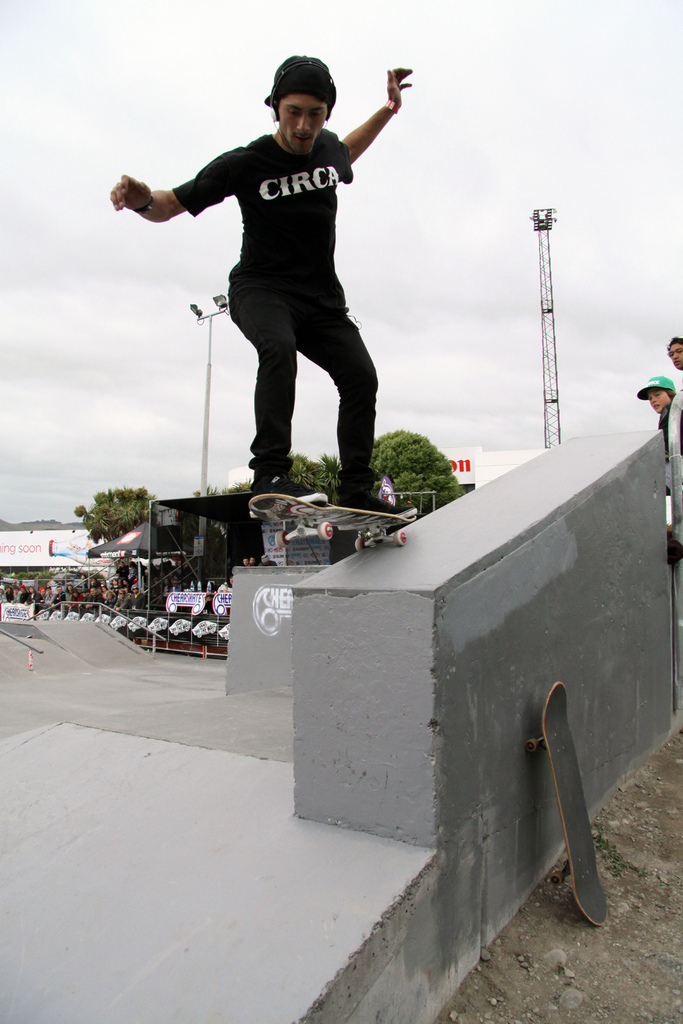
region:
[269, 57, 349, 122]
Boy wearing black hat.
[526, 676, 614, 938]
Skateboard leaning on wall.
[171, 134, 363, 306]
Boy wearing black shirt.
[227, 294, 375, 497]
Boy wearing black pants.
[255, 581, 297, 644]
White letters on wall.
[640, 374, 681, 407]
Person wearing green hat.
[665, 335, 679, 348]
Person has dark hair.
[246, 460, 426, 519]
Person wearing black tennis shoes.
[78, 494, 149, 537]
Green leaves on tree in distance.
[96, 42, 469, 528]
a guy doing a trick on a skateboard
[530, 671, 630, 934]
a skateboard leaning against the wall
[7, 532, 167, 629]
spectators sitting in a stand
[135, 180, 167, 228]
a black watch band on his wrist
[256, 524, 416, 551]
white and red wheels on the skateboard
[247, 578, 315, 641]
white letters painted on the wall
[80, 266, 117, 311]
white clouds in blue sky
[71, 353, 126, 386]
white clouds in blue sky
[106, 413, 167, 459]
white clouds in blue sky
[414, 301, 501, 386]
white clouds in blue sky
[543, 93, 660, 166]
white clouds in blue sky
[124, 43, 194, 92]
white clouds in blue sky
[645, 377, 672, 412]
person has a head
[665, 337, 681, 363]
person has a head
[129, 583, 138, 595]
person has a head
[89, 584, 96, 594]
person has a head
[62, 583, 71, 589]
person has a head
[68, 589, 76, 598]
person has a head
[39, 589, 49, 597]
person has a head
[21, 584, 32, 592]
person has a head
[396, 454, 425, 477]
green leaves on the tree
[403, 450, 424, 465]
green leaves on the tree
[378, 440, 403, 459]
green leaves on the tree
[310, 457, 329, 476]
green leaves on the tree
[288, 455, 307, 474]
green leaves on the tree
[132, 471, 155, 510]
green leaves on the tree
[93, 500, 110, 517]
green leaves on the tree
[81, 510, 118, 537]
green leaves on the tree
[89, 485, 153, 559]
green leaves on the tree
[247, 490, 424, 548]
skate board rolling down the cement wall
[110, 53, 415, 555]
man skateboarding down the wall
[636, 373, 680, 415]
boy wearing a green cap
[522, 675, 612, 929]
skateboard leaning against cement wall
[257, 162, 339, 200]
white letters on black t-shirt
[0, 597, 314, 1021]
professional cement skateboarding course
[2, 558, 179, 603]
spectators sitting in the bleachers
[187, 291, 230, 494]
tall metal light poles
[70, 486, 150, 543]
a green tree beside sign